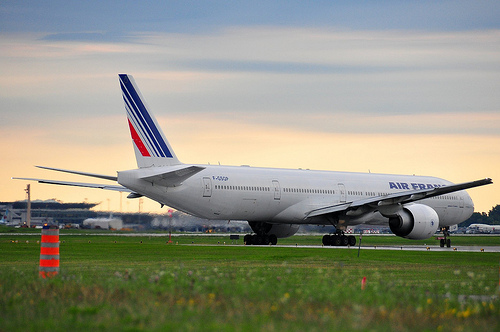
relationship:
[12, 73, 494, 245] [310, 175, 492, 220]
plane has wing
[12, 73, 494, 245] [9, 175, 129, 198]
plane has wing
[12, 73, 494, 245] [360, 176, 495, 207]
plane has wing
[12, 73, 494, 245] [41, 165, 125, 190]
plane has wing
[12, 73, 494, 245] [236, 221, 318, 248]
plane has wheel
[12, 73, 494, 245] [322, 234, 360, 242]
plane has wheel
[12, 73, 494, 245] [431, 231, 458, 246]
plane has wheel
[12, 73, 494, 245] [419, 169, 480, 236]
plane has front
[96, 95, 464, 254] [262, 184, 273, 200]
plane has window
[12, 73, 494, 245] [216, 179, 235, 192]
plane has window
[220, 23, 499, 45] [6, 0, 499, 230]
clouds are in sky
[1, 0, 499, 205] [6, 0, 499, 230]
clouds are in sky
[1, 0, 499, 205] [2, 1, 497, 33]
clouds in sky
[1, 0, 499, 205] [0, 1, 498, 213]
clouds are in blue sky